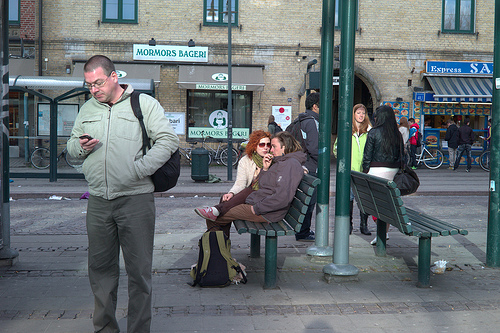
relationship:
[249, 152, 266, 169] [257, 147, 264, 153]
scarf around neck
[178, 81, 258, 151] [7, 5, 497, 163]
window on building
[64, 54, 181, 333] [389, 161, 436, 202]
man carrying backpack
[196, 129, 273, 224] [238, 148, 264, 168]
woman wearing scarf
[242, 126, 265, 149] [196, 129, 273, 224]
hair of woman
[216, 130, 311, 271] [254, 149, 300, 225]
man wearing sweatshirt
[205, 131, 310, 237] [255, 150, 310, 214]
man wearing sweatshirt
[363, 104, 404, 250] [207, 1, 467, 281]
woman at bus stop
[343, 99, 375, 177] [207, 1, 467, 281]
woman at bus stop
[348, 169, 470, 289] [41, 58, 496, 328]
bench at bus stop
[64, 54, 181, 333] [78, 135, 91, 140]
man looking at cell phone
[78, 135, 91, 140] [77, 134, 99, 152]
cell phone in hand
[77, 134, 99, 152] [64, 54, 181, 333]
hand of man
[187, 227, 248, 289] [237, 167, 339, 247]
backpack near bench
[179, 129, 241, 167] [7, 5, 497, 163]
bicycle leaning against building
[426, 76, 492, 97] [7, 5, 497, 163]
awning on building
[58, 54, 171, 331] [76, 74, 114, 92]
man wearing eye glasses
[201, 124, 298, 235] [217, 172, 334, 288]
people sitting on bench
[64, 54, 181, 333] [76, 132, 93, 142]
man using phone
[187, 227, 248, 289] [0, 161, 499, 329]
backpack on ground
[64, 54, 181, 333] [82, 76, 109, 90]
man wearing glasses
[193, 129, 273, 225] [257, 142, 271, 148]
woman wearing glasses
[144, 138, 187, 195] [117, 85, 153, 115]
backpack over shoulder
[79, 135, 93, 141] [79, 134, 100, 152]
cell phone in hand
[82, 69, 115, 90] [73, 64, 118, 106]
eye glasses are on man's face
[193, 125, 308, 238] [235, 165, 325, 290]
people are on bench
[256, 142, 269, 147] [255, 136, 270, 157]
glasses are on face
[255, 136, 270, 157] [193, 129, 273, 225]
face on woman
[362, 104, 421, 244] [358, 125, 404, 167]
woman wearing jacket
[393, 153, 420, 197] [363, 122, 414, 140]
backpack on shoulder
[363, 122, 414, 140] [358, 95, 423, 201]
shoulder on woman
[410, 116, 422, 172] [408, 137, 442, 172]
man on bicycle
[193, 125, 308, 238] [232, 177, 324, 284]
people on bench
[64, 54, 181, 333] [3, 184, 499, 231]
man on street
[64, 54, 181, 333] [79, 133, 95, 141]
man looking at phone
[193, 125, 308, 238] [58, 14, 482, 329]
people waiting at bus stop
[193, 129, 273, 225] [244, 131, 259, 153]
woman with hair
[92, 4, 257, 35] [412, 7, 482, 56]
windows with green frames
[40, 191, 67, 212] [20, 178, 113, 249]
garbage in street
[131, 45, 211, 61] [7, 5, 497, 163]
sign on building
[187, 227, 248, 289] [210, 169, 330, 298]
backpack beside bench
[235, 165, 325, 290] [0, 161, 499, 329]
bench on ground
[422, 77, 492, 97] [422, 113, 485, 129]
awning over window